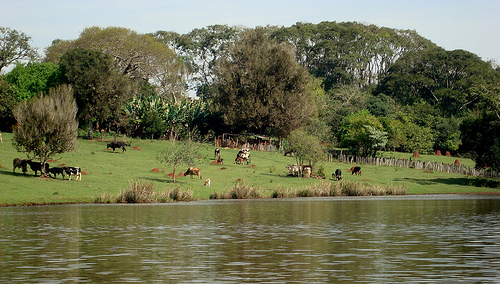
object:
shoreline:
[0, 191, 499, 208]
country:
[0, 19, 500, 207]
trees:
[186, 25, 323, 151]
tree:
[7, 81, 81, 182]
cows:
[331, 168, 344, 181]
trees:
[282, 124, 330, 178]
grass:
[118, 178, 157, 204]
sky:
[0, 1, 500, 102]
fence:
[213, 132, 500, 182]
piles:
[166, 172, 178, 178]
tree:
[457, 115, 500, 176]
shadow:
[392, 176, 500, 190]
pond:
[0, 191, 500, 284]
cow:
[61, 166, 83, 182]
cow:
[234, 148, 252, 165]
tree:
[154, 138, 215, 185]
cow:
[302, 164, 312, 179]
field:
[6, 132, 482, 196]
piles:
[150, 168, 160, 173]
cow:
[183, 166, 203, 180]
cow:
[25, 158, 50, 178]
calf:
[202, 178, 211, 188]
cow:
[105, 140, 129, 154]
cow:
[213, 147, 221, 161]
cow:
[350, 166, 363, 177]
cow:
[285, 163, 304, 177]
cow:
[11, 157, 28, 175]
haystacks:
[132, 146, 142, 151]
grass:
[0, 132, 500, 204]